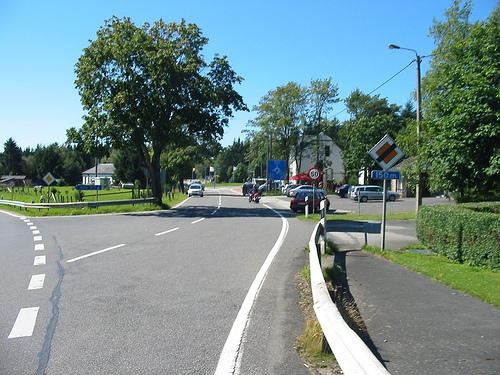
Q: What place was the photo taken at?
A: It was taken at the road.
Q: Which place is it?
A: It is a road.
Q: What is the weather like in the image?
A: It is clear.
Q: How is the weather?
A: It is clear.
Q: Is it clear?
A: Yes, it is clear.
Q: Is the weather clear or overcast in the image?
A: It is clear.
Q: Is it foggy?
A: No, it is clear.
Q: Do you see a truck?
A: No, there are no trucks.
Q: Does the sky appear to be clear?
A: Yes, the sky is clear.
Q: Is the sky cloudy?
A: No, the sky is clear.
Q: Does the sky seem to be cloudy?
A: No, the sky is clear.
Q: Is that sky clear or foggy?
A: The sky is clear.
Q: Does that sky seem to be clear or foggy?
A: The sky is clear.